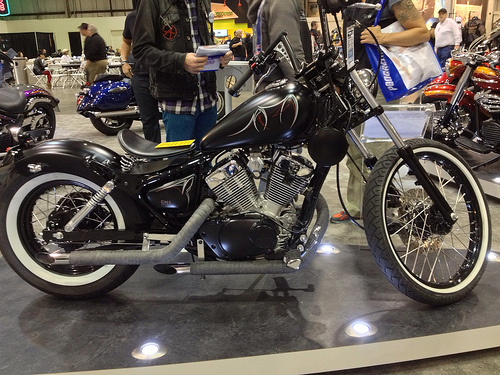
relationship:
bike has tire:
[2, 77, 60, 155] [19, 97, 62, 142]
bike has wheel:
[0, 3, 490, 305] [2, 152, 149, 306]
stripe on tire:
[4, 176, 33, 269] [0, 160, 143, 298]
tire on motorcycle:
[0, 160, 143, 298] [1, 0, 488, 307]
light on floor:
[131, 340, 165, 361] [2, 284, 473, 372]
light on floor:
[343, 312, 377, 340] [2, 284, 473, 372]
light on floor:
[125, 335, 172, 366] [0, 70, 499, 372]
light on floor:
[343, 317, 377, 338] [0, 70, 499, 372]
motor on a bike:
[207, 148, 315, 218] [0, 3, 490, 305]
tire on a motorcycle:
[365, 140, 490, 303] [1, 0, 488, 307]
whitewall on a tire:
[383, 146, 490, 291] [365, 140, 490, 303]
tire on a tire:
[0, 160, 143, 298] [0, 160, 143, 298]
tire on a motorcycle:
[0, 160, 143, 298] [1, 0, 488, 307]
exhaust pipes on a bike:
[50, 191, 330, 272] [0, 3, 490, 306]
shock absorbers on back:
[63, 179, 117, 233] [3, 128, 173, 298]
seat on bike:
[116, 123, 192, 157] [0, 3, 490, 306]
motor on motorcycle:
[207, 154, 310, 223] [1, 0, 488, 307]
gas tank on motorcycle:
[190, 80, 319, 152] [1, 0, 488, 307]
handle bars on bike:
[227, 3, 385, 95] [0, 3, 490, 306]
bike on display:
[0, 3, 490, 306] [3, 225, 499, 372]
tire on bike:
[365, 140, 490, 303] [0, 3, 490, 306]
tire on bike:
[3, 160, 139, 298] [0, 3, 490, 306]